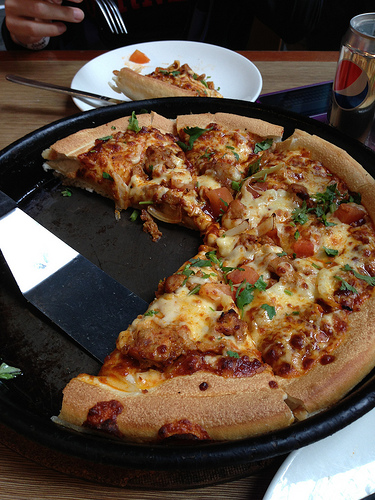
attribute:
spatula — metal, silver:
[0, 186, 154, 365]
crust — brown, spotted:
[50, 371, 297, 446]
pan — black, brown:
[0, 96, 373, 467]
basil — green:
[311, 185, 338, 220]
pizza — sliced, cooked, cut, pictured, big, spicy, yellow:
[42, 110, 374, 444]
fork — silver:
[93, 1, 131, 37]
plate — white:
[69, 38, 265, 111]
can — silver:
[325, 10, 375, 154]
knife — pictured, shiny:
[4, 70, 126, 104]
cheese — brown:
[161, 291, 199, 327]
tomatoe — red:
[291, 235, 314, 258]